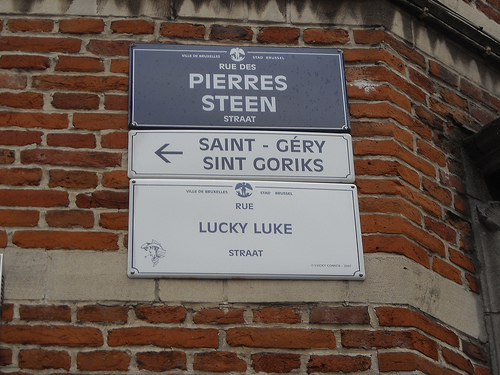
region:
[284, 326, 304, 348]
part of a brick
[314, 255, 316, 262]
part of a board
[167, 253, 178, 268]
edge of a board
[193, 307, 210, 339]
edge of a brick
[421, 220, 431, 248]
side of a wall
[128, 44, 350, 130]
grey sign on wall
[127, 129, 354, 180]
white and grey sign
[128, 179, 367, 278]
white sign on wall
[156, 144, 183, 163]
arrow symbol on sign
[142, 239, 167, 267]
decal on white sign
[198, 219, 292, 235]
grey letters on sign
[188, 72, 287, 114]
white letters on sign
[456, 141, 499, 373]
brown window on building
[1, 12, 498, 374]
red brick building wall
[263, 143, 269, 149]
grey line on sign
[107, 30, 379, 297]
signs on front of brick building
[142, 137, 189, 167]
black arrow on sign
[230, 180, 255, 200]
logo image on sign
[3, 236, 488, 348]
tan concrete strip on brick building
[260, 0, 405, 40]
dark stains at top of building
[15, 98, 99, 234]
red brick on side of building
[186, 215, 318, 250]
name on sign on building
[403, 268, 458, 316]
dark stain on concrete strip on side of building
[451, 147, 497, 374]
stone lining on side of building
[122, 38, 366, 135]
grey sign on side of building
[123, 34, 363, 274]
three signs attached to the building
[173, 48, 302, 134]
white lettering on gray sign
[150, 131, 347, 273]
gray lettering on white sign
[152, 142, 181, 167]
gray arrow on white sign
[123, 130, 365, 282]
gray borders on white signs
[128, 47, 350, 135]
white border on gray sign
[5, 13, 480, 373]
red brick wall signs are affixed to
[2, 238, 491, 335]
cement line between the rbicks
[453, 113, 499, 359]
edge of window frame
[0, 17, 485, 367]
brick wall signs are affixed to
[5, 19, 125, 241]
brick siding on building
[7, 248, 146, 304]
cement blocks on the buliding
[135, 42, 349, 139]
dark blue sign on building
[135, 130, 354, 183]
small white and blue sign hanging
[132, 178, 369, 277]
a white and blue sign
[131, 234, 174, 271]
logo on the sign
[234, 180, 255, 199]
eagle emblem on sign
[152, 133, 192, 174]
a blue arrow on sign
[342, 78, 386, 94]
discoloration on the bricks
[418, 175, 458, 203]
a brick on the building